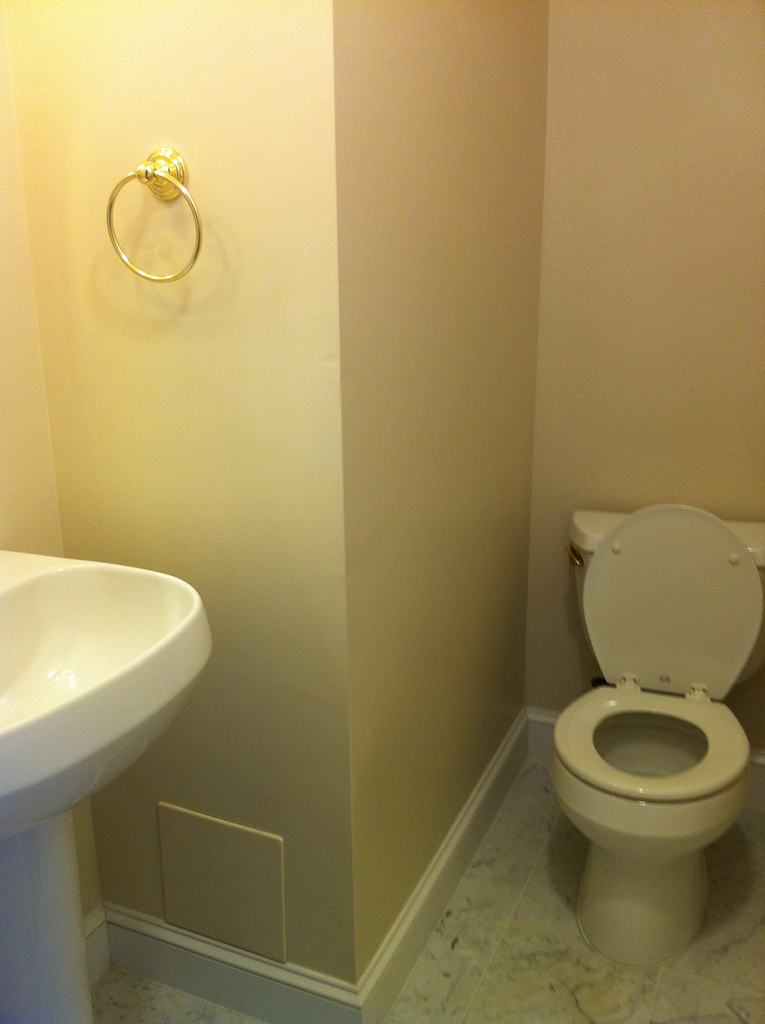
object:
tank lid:
[563, 503, 765, 560]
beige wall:
[24, 0, 361, 1024]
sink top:
[0, 548, 217, 828]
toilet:
[553, 484, 765, 971]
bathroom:
[0, 0, 765, 1024]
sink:
[0, 548, 215, 1024]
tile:
[88, 703, 765, 1024]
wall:
[0, 0, 353, 997]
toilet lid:
[583, 501, 765, 699]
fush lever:
[565, 544, 584, 566]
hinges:
[614, 663, 716, 702]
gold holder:
[105, 147, 203, 284]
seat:
[551, 684, 751, 864]